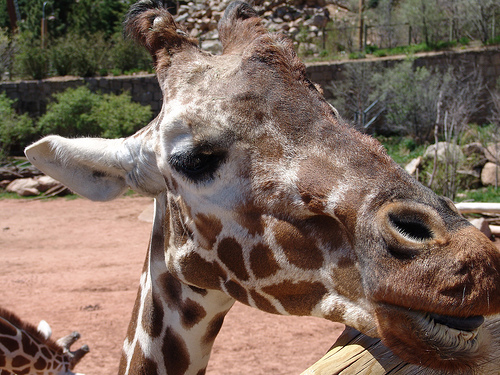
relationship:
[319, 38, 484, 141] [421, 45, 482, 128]
trees have no leaves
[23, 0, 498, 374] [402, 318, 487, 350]
giraffe has tongue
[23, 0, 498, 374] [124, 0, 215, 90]
giraffe has horn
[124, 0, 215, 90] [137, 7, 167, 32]
horn has tip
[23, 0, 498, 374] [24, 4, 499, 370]
giraffe has giraffe's head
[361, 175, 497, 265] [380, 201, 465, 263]
nose has nostril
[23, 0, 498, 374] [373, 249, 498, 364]
giraffe has mouth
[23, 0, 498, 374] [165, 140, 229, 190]
giraffe has brown eye